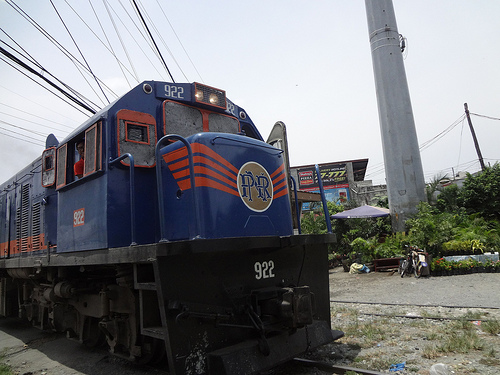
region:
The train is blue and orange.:
[0, 81, 332, 255]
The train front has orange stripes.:
[166, 140, 290, 202]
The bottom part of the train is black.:
[0, 233, 344, 373]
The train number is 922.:
[162, 81, 187, 102]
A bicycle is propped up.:
[398, 242, 428, 277]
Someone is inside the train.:
[71, 138, 87, 176]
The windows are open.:
[56, 121, 101, 188]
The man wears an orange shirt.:
[73, 155, 85, 177]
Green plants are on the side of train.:
[303, 162, 498, 252]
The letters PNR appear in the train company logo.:
[235, 170, 273, 199]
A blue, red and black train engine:
[12, 77, 349, 368]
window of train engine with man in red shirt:
[70, 138, 85, 180]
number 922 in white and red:
[70, 208, 89, 227]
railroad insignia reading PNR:
[237, 159, 276, 215]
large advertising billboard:
[293, 157, 372, 189]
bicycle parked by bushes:
[399, 243, 429, 280]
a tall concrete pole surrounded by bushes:
[363, 0, 438, 245]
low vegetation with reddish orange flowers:
[435, 255, 497, 272]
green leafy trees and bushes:
[431, 170, 498, 252]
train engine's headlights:
[190, 87, 225, 105]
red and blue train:
[50, 119, 273, 272]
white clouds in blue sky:
[176, 16, 252, 55]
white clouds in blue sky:
[54, 27, 138, 68]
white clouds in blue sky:
[16, 92, 63, 125]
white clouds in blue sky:
[211, 11, 252, 52]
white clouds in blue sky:
[262, 0, 323, 60]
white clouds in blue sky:
[249, 65, 306, 98]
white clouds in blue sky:
[304, 63, 346, 115]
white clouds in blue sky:
[416, 16, 485, 63]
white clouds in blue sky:
[430, 73, 479, 103]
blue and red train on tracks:
[3, 80, 345, 370]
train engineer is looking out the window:
[65, 137, 87, 183]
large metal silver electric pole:
[359, 3, 432, 251]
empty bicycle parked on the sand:
[396, 241, 433, 279]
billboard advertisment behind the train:
[288, 156, 370, 193]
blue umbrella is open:
[329, 203, 389, 228]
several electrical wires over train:
[4, 6, 209, 90]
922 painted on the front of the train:
[250, 255, 276, 280]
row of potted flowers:
[428, 255, 497, 279]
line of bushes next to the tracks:
[310, 197, 475, 260]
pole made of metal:
[348, 4, 459, 239]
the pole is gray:
[353, 1, 452, 242]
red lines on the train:
[140, 128, 335, 212]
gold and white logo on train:
[226, 162, 286, 214]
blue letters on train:
[226, 158, 276, 207]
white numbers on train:
[139, 71, 193, 108]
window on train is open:
[45, 123, 117, 190]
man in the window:
[51, 131, 95, 178]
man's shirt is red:
[58, 153, 101, 188]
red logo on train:
[67, 198, 93, 236]